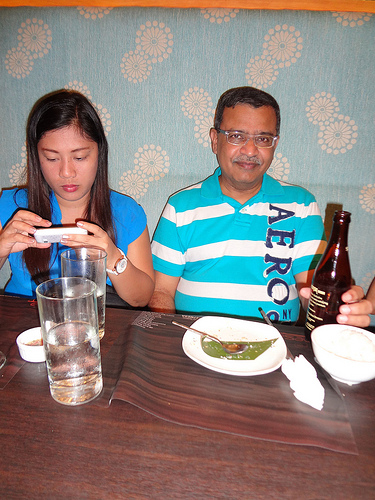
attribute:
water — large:
[26, 268, 107, 400]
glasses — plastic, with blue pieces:
[227, 131, 275, 148]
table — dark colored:
[0, 285, 373, 498]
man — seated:
[152, 82, 354, 319]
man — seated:
[154, 79, 371, 325]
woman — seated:
[3, 86, 156, 308]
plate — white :
[181, 314, 288, 377]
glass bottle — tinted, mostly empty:
[306, 210, 355, 338]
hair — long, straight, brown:
[23, 91, 116, 281]